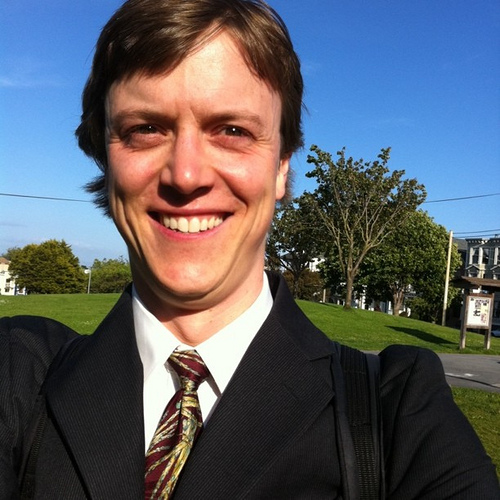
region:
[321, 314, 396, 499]
Black shoulder strap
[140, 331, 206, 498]
Red and gold tie with Windsor knot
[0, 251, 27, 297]
white building with brown roof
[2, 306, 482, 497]
black suit jacket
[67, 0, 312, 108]
straight medium brown hair parted on left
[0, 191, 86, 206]
black power line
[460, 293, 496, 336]
sign board with small notices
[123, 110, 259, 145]
Brown eyes slightly squinting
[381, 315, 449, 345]
shadow of sign board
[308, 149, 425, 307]
tall deciduous trees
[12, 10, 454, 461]
man with a very big smile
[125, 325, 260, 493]
burgandy and gold tie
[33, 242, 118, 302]
flag in the hole at golf course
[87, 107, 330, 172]
wrinkles around eyes from aging and sun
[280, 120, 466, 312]
cluster of large shade trees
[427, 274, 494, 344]
brown and white sign on lawn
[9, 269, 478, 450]
white dress shirt under black suit jacket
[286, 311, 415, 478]
one of the straps from a backpack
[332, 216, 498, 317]
building in back appears to be apartments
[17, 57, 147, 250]
hair flipping away at the side of his head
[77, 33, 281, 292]
a man with a very large smile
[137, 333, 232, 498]
a red and gold tie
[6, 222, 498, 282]
several trees in back ground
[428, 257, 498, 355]
there is a sign with signs hanging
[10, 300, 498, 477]
a man in a dark suit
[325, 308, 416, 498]
a strap to a bag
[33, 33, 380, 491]
a man in a selfie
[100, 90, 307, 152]
the man has dark eyes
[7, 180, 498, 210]
a power or phone line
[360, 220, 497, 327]
an apartment building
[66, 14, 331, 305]
a man with brown hair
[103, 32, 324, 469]
a man wearing a tie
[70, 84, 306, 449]
a man wearing a white shirt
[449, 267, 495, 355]
a wooden sign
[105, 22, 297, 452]
a man wearing a black jacket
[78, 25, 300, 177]
a man with brown eyes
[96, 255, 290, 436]
a white dress shirt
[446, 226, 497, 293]
a grey building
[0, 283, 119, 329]
a field of green grass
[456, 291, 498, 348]
monument sign in the background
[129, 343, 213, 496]
multi-colored necktie on a man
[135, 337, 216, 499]
multi-colored necktie on a young man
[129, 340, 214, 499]
multi-colored necktie on a person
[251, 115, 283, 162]
wrinkles at the edge of the eyes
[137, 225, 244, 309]
a sharp chin on a guy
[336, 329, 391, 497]
a strap on the shoulder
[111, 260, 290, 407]
white collar with a tie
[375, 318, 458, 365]
shadow of the monument sign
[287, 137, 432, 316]
a tree on the hillside